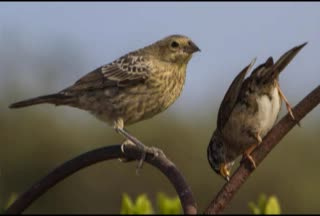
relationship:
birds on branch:
[7, 31, 310, 178] [7, 84, 318, 208]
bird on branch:
[6, 33, 200, 173] [7, 84, 318, 208]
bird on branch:
[206, 39, 309, 183] [7, 84, 318, 208]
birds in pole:
[7, 34, 307, 183] [0, 86, 320, 216]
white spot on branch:
[173, 179, 201, 199] [30, 133, 198, 203]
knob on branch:
[208, 187, 239, 211] [7, 84, 318, 208]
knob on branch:
[164, 160, 175, 176] [1, 143, 197, 214]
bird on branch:
[6, 33, 200, 173] [68, 147, 148, 162]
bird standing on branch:
[8, 35, 202, 175] [66, 147, 166, 169]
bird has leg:
[6, 33, 200, 173] [121, 128, 158, 160]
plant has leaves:
[2, 85, 319, 215] [117, 188, 180, 215]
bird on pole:
[206, 39, 309, 183] [0, 82, 319, 214]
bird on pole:
[6, 33, 200, 173] [0, 82, 319, 214]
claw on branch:
[136, 147, 165, 172] [1, 143, 197, 214]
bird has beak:
[6, 33, 200, 173] [185, 40, 200, 53]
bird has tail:
[8, 35, 202, 175] [9, 91, 71, 105]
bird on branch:
[206, 39, 309, 183] [43, 34, 290, 205]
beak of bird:
[187, 42, 200, 52] [8, 34, 200, 148]